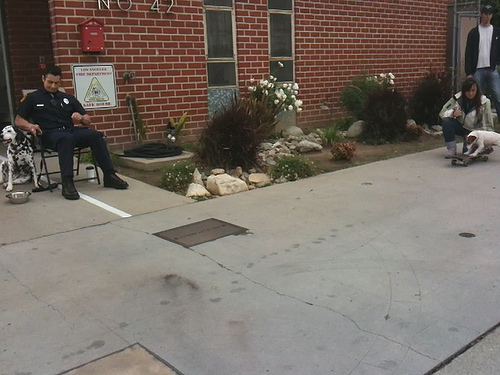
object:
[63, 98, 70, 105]
badge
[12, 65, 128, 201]
cop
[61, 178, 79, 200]
shoes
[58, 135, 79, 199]
feet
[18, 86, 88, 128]
shirt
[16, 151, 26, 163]
dalmation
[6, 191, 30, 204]
dog bowl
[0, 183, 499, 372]
ground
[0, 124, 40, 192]
dog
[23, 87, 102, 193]
chair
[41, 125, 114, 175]
pants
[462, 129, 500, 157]
dog